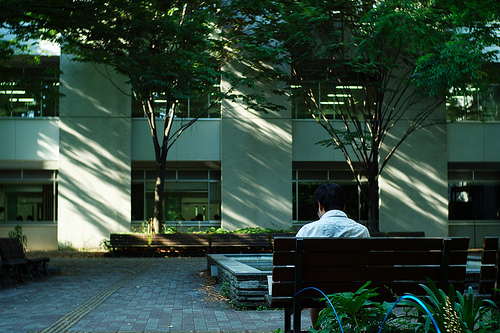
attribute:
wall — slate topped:
[202, 246, 276, 305]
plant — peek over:
[297, 282, 384, 332]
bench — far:
[106, 234, 150, 255]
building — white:
[1, 0, 499, 250]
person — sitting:
[289, 180, 375, 332]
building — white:
[4, 22, 499, 313]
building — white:
[5, 38, 498, 240]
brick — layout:
[139, 278, 194, 319]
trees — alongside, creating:
[6, 5, 492, 236]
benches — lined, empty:
[108, 232, 273, 251]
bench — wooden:
[261, 233, 476, 328]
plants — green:
[307, 280, 499, 331]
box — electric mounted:
[207, 266, 218, 278]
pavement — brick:
[1, 257, 296, 331]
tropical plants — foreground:
[307, 277, 498, 331]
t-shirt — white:
[287, 210, 377, 240]